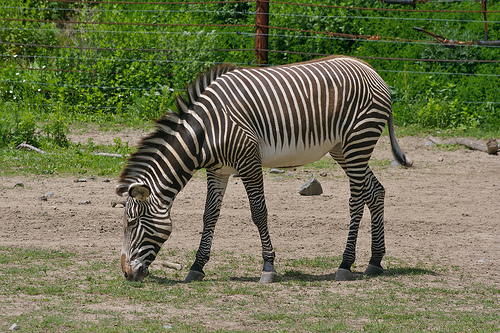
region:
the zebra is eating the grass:
[106, 193, 175, 279]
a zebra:
[113, 68, 403, 279]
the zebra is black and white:
[98, 56, 415, 274]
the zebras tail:
[383, 118, 418, 169]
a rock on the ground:
[298, 178, 323, 196]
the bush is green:
[70, 28, 190, 100]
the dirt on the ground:
[408, 178, 499, 260]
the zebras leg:
[197, 183, 290, 282]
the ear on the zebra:
[127, 182, 157, 202]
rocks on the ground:
[13, 178, 103, 209]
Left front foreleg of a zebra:
[239, 150, 286, 285]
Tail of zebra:
[386, 90, 417, 170]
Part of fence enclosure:
[5, 15, 159, 123]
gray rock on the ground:
[296, 178, 327, 199]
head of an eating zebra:
[119, 179, 173, 290]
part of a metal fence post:
[254, 0, 275, 77]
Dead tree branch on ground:
[421, 130, 497, 153]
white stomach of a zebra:
[260, 143, 332, 165]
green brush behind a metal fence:
[14, 10, 492, 108]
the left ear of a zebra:
[128, 181, 152, 197]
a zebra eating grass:
[102, 60, 417, 286]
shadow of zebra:
[181, 260, 443, 285]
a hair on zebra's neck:
[118, 135, 192, 176]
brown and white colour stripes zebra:
[155, 65, 393, 168]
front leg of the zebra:
[244, 164, 284, 293]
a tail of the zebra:
[384, 113, 418, 169]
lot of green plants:
[21, 47, 151, 110]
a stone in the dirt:
[297, 175, 329, 199]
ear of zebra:
[126, 178, 151, 205]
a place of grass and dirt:
[19, 245, 79, 312]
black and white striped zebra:
[98, 49, 406, 291]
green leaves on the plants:
[13, 16, 75, 66]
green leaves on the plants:
[26, 71, 64, 106]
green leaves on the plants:
[38, 23, 106, 68]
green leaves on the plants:
[63, 57, 121, 112]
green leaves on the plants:
[122, 16, 187, 70]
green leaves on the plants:
[393, 64, 451, 101]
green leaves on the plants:
[446, 103, 481, 133]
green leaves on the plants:
[352, 16, 409, 53]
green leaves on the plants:
[419, 16, 473, 80]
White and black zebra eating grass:
[109, 50, 413, 285]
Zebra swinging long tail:
[110, 53, 415, 290]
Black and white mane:
[115, 53, 235, 187]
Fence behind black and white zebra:
[0, 0, 499, 144]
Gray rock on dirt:
[298, 178, 324, 195]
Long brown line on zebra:
[238, 65, 279, 152]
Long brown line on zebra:
[266, 65, 301, 151]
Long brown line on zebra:
[290, 62, 317, 153]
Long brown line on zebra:
[305, 61, 327, 144]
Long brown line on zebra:
[197, 90, 226, 173]